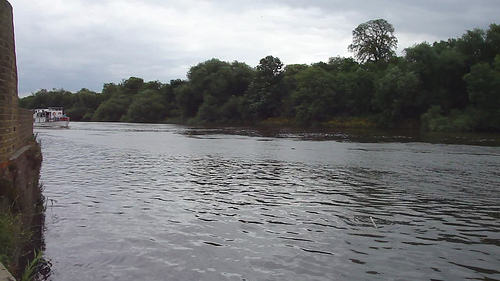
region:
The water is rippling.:
[31, 106, 499, 279]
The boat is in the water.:
[27, 103, 498, 279]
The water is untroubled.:
[27, 105, 497, 277]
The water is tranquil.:
[30, 100, 495, 272]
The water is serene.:
[23, 103, 496, 278]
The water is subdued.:
[26, 108, 497, 279]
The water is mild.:
[28, 103, 497, 279]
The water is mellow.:
[23, 105, 495, 278]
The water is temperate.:
[21, 107, 499, 279]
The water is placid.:
[24, 98, 498, 279]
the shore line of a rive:
[66, 109, 498, 141]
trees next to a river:
[18, 19, 496, 136]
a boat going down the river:
[31, 104, 72, 127]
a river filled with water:
[31, 110, 498, 277]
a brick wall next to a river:
[0, 0, 55, 278]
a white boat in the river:
[30, 107, 72, 133]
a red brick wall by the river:
[0, 0, 53, 280]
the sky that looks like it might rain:
[9, 1, 493, 98]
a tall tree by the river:
[349, 17, 402, 71]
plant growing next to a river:
[16, 249, 55, 280]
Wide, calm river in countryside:
[31, 119, 497, 277]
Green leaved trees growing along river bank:
[20, 17, 497, 137]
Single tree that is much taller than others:
[347, 16, 399, 63]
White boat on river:
[30, 105, 72, 127]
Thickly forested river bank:
[18, 21, 497, 131]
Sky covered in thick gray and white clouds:
[7, 2, 497, 99]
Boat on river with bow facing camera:
[30, 105, 72, 130]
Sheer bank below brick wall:
[2, 165, 46, 275]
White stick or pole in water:
[366, 213, 378, 228]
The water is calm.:
[144, 193, 277, 273]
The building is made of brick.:
[4, 105, 29, 149]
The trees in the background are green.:
[281, 71, 391, 111]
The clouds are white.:
[246, 25, 316, 45]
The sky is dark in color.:
[413, 2, 464, 27]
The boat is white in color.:
[33, 105, 71, 127]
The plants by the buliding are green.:
[7, 191, 44, 268]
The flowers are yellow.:
[328, 117, 369, 127]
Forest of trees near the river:
[22, 19, 499, 135]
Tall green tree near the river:
[348, 17, 399, 63]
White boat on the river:
[32, 105, 71, 127]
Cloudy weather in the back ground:
[9, 1, 498, 100]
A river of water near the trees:
[28, 120, 498, 280]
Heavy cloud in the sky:
[285, 0, 497, 37]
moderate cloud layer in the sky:
[19, 69, 106, 94]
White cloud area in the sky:
[138, 0, 356, 65]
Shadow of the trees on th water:
[188, 120, 498, 149]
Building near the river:
[1, 2, 42, 216]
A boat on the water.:
[31, 109, 66, 128]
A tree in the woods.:
[350, 17, 406, 69]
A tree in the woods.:
[247, 53, 276, 79]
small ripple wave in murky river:
[235, 214, 261, 229]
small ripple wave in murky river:
[347, 253, 366, 268]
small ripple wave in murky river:
[347, 246, 369, 256]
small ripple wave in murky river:
[340, 224, 387, 240]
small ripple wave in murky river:
[444, 255, 498, 276]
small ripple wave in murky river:
[254, 196, 289, 209]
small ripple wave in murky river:
[138, 191, 153, 199]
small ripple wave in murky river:
[468, 186, 495, 198]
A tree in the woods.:
[348, 19, 406, 65]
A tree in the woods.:
[457, 65, 489, 112]